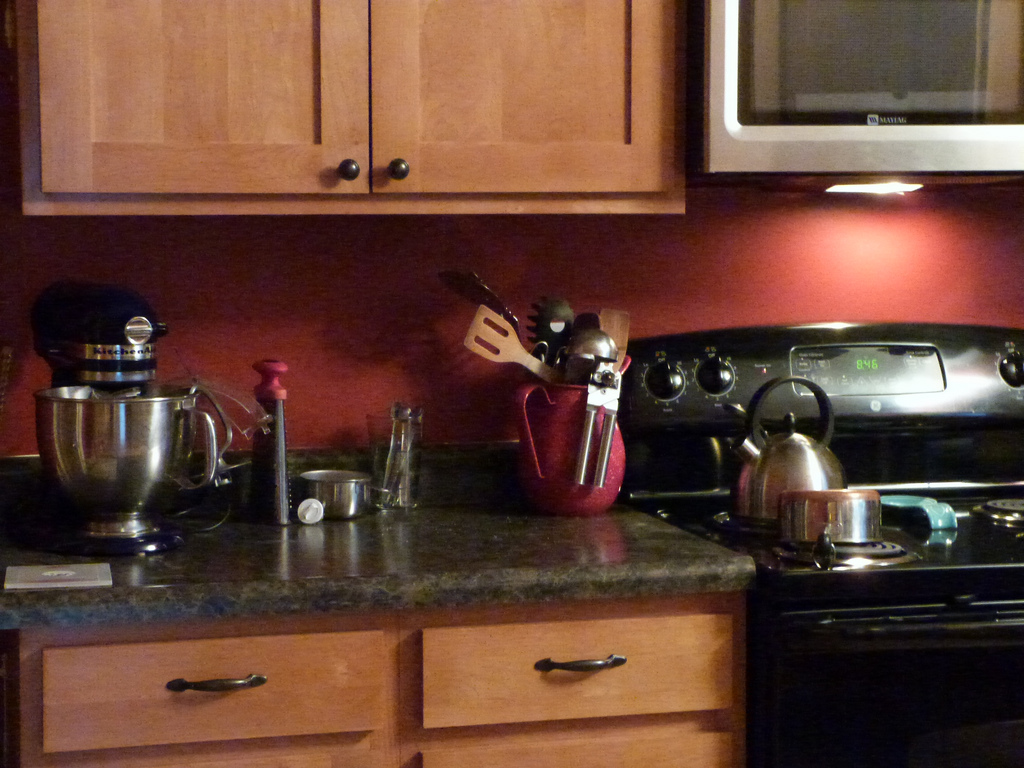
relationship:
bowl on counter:
[0, 272, 231, 558] [22, 500, 755, 637]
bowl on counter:
[285, 446, 384, 529] [11, 489, 770, 637]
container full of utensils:
[486, 356, 642, 527] [424, 230, 654, 486]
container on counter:
[486, 356, 642, 527] [14, 476, 766, 634]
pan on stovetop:
[772, 482, 902, 562] [590, 312, 994, 609]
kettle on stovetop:
[726, 371, 847, 551] [661, 473, 1020, 586]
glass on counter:
[369, 430, 428, 511] [7, 488, 766, 659]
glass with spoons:
[369, 430, 428, 511] [378, 395, 437, 499]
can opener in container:
[570, 341, 640, 499] [486, 356, 642, 527]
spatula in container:
[454, 298, 563, 376] [486, 356, 642, 527]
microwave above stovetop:
[676, 0, 1024, 208] [622, 318, 1016, 762]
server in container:
[525, 287, 584, 372] [486, 356, 642, 527]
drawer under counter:
[28, 615, 400, 758] [7, 436, 766, 640]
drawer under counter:
[408, 601, 750, 748] [7, 436, 766, 640]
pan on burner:
[766, 473, 925, 572] [788, 533, 912, 577]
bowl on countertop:
[0, 272, 231, 558] [4, 458, 771, 647]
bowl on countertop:
[285, 446, 384, 529] [7, 475, 766, 644]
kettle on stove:
[710, 356, 855, 551] [618, 313, 1012, 759]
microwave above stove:
[696, 0, 1018, 186] [618, 313, 1012, 759]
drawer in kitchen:
[408, 601, 750, 748] [7, 6, 1016, 758]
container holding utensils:
[497, 348, 644, 526] [437, 257, 639, 372]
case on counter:
[4, 551, 119, 595] [7, 436, 766, 640]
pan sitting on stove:
[766, 473, 925, 572] [618, 313, 1012, 759]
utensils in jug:
[444, 265, 630, 486] [513, 379, 630, 518]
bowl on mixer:
[36, 384, 218, 540] [27, 276, 218, 540]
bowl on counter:
[299, 464, 369, 519] [5, 453, 757, 631]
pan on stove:
[766, 473, 925, 572] [618, 313, 1012, 759]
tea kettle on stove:
[723, 373, 844, 525] [618, 313, 1012, 759]